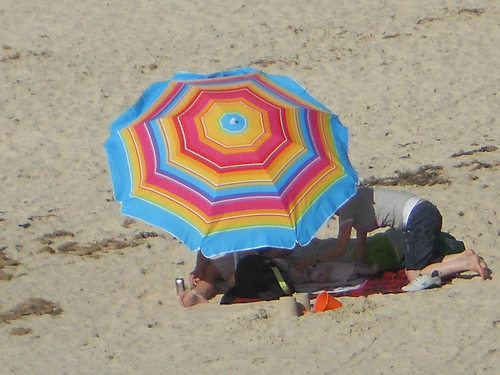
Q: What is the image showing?
A: It is showing a beach.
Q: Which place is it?
A: It is a beach.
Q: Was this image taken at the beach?
A: Yes, it was taken in the beach.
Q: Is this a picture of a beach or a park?
A: It is showing a beach.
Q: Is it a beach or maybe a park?
A: It is a beach.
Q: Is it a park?
A: No, it is a beach.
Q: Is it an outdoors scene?
A: Yes, it is outdoors.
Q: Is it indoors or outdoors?
A: It is outdoors.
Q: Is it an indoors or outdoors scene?
A: It is outdoors.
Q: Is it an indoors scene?
A: No, it is outdoors.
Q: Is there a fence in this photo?
A: No, there are no fences.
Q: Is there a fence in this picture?
A: No, there are no fences.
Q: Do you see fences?
A: No, there are no fences.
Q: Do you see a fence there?
A: No, there are no fences.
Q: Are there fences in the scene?
A: No, there are no fences.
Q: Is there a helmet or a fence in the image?
A: No, there are no fences or helmets.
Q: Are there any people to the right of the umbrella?
A: Yes, there is a person to the right of the umbrella.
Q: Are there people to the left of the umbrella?
A: No, the person is to the right of the umbrella.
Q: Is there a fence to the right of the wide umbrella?
A: No, there is a person to the right of the umbrella.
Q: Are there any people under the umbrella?
A: Yes, there is a person under the umbrella.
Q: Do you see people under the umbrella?
A: Yes, there is a person under the umbrella.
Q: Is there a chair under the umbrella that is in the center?
A: No, there is a person under the umbrella.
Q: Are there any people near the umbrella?
A: Yes, there is a person near the umbrella.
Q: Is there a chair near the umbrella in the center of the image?
A: No, there is a person near the umbrella.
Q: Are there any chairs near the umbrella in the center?
A: No, there is a person near the umbrella.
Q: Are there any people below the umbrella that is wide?
A: Yes, there is a person below the umbrella.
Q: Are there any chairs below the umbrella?
A: No, there is a person below the umbrella.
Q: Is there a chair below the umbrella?
A: No, there is a person below the umbrella.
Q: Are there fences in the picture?
A: No, there are no fences.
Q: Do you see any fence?
A: No, there are no fences.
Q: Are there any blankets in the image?
A: Yes, there is a blanket.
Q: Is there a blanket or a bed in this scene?
A: Yes, there is a blanket.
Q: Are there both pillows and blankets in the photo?
A: No, there is a blanket but no pillows.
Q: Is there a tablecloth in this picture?
A: No, there are no tablecloths.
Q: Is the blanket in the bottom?
A: Yes, the blanket is in the bottom of the image.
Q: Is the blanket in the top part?
A: No, the blanket is in the bottom of the image.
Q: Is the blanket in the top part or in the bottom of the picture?
A: The blanket is in the bottom of the image.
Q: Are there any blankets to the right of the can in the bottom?
A: Yes, there is a blanket to the right of the can.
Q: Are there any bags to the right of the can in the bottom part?
A: No, there is a blanket to the right of the can.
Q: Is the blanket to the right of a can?
A: Yes, the blanket is to the right of a can.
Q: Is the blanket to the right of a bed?
A: No, the blanket is to the right of a can.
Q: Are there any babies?
A: Yes, there is a baby.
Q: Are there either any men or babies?
A: Yes, there is a baby.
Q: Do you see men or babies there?
A: Yes, there is a baby.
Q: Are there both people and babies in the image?
A: Yes, there are both a baby and people.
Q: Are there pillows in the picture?
A: No, there are no pillows.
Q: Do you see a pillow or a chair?
A: No, there are no pillows or chairs.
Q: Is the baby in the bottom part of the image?
A: Yes, the baby is in the bottom of the image.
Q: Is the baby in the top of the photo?
A: No, the baby is in the bottom of the image.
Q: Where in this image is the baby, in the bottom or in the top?
A: The baby is in the bottom of the image.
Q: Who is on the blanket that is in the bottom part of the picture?
A: The baby is on the blanket.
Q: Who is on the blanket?
A: The baby is on the blanket.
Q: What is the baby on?
A: The baby is on the blanket.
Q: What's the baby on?
A: The baby is on the blanket.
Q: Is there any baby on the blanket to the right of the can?
A: Yes, there is a baby on the blanket.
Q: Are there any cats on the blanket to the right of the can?
A: No, there is a baby on the blanket.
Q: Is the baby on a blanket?
A: Yes, the baby is on a blanket.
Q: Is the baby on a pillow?
A: No, the baby is on a blanket.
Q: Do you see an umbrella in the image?
A: Yes, there is an umbrella.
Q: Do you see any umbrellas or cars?
A: Yes, there is an umbrella.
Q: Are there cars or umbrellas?
A: Yes, there is an umbrella.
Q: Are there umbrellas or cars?
A: Yes, there is an umbrella.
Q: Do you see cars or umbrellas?
A: Yes, there is an umbrella.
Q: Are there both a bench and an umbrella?
A: No, there is an umbrella but no benches.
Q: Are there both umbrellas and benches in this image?
A: No, there is an umbrella but no benches.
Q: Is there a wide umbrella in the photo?
A: Yes, there is a wide umbrella.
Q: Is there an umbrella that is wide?
A: Yes, there is an umbrella that is wide.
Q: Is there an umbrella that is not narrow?
A: Yes, there is a wide umbrella.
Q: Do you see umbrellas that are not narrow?
A: Yes, there is a wide umbrella.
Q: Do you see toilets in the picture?
A: No, there are no toilets.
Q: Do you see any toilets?
A: No, there are no toilets.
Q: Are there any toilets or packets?
A: No, there are no toilets or packets.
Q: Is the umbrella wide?
A: Yes, the umbrella is wide.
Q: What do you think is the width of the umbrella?
A: The umbrella is wide.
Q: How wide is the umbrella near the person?
A: The umbrella is wide.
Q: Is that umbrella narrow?
A: No, the umbrella is wide.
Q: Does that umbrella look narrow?
A: No, the umbrella is wide.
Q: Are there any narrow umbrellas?
A: No, there is an umbrella but it is wide.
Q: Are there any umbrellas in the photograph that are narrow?
A: No, there is an umbrella but it is wide.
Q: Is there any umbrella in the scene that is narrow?
A: No, there is an umbrella but it is wide.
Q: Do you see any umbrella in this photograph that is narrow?
A: No, there is an umbrella but it is wide.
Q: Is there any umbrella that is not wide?
A: No, there is an umbrella but it is wide.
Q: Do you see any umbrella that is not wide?
A: No, there is an umbrella but it is wide.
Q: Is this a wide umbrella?
A: Yes, this is a wide umbrella.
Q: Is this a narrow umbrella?
A: No, this is a wide umbrella.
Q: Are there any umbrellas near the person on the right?
A: Yes, there is an umbrella near the person.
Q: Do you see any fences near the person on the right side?
A: No, there is an umbrella near the person.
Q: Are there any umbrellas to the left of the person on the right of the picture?
A: Yes, there is an umbrella to the left of the person.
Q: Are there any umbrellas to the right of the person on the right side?
A: No, the umbrella is to the left of the person.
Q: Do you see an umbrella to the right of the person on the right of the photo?
A: No, the umbrella is to the left of the person.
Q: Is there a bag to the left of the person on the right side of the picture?
A: No, there is an umbrella to the left of the person.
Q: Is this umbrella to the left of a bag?
A: No, the umbrella is to the left of the person.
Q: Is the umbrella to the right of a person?
A: No, the umbrella is to the left of a person.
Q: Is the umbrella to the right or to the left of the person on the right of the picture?
A: The umbrella is to the left of the person.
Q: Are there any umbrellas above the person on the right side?
A: Yes, there is an umbrella above the person.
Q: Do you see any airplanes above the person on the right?
A: No, there is an umbrella above the person.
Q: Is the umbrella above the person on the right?
A: Yes, the umbrella is above the person.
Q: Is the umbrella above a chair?
A: No, the umbrella is above the person.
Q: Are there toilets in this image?
A: No, there are no toilets.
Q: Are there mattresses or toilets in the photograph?
A: No, there are no toilets or mattresses.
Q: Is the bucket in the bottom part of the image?
A: Yes, the bucket is in the bottom of the image.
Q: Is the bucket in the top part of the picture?
A: No, the bucket is in the bottom of the image.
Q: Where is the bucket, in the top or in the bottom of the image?
A: The bucket is in the bottom of the image.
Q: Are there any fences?
A: No, there are no fences.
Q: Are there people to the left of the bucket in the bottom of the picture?
A: Yes, there is a person to the left of the bucket.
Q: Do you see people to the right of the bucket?
A: No, the person is to the left of the bucket.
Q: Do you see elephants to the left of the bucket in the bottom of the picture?
A: No, there is a person to the left of the bucket.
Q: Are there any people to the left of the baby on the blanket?
A: Yes, there is a person to the left of the baby.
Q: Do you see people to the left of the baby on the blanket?
A: Yes, there is a person to the left of the baby.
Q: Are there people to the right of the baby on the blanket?
A: No, the person is to the left of the baby.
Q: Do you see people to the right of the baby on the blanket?
A: No, the person is to the left of the baby.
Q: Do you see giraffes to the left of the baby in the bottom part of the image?
A: No, there is a person to the left of the baby.